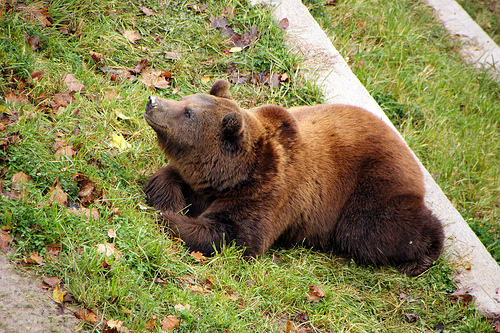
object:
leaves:
[10, 171, 34, 193]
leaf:
[44, 183, 68, 207]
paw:
[150, 207, 188, 236]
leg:
[155, 193, 286, 263]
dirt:
[1, 237, 95, 333]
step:
[249, 1, 500, 322]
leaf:
[112, 109, 137, 122]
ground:
[0, 0, 499, 333]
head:
[140, 79, 258, 192]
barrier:
[253, 0, 378, 105]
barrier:
[421, 0, 498, 96]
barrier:
[421, 157, 497, 332]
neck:
[221, 96, 275, 198]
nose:
[143, 93, 161, 110]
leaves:
[100, 64, 139, 83]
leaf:
[137, 203, 148, 210]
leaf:
[65, 73, 86, 93]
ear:
[210, 78, 232, 97]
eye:
[184, 111, 191, 119]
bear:
[143, 79, 444, 277]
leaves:
[108, 133, 132, 150]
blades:
[182, 250, 210, 262]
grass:
[0, 1, 498, 331]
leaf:
[58, 72, 88, 96]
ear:
[221, 112, 245, 138]